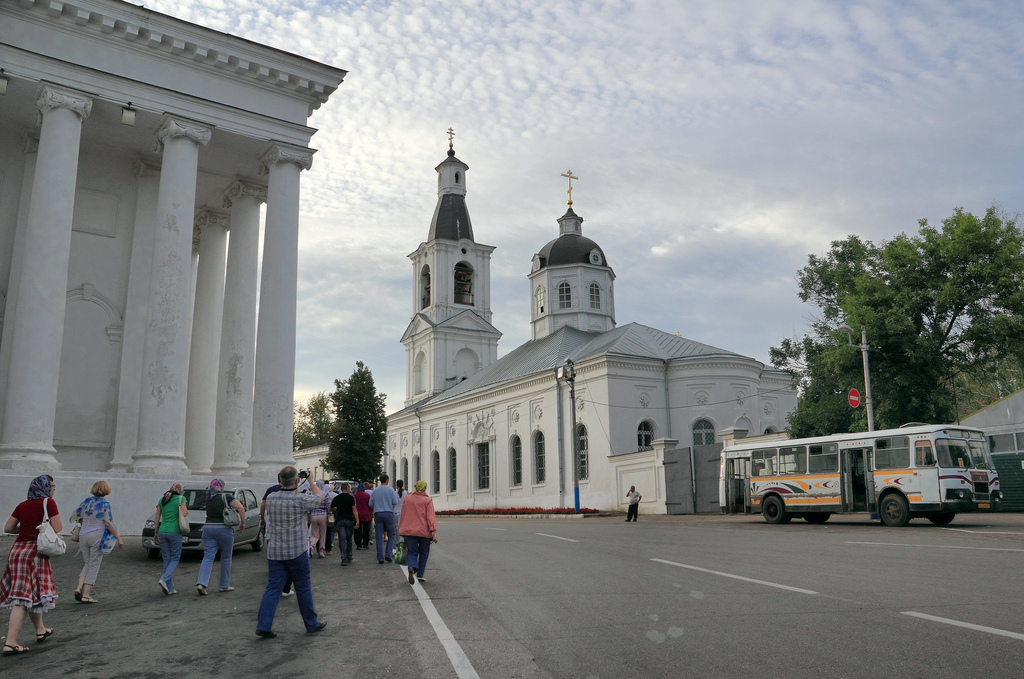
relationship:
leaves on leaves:
[793, 351, 841, 425] [769, 206, 1024, 439]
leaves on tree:
[872, 322, 912, 403] [786, 199, 1013, 433]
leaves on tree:
[816, 240, 883, 325] [786, 199, 1013, 433]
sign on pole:
[842, 381, 868, 407] [849, 329, 882, 436]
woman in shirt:
[149, 474, 189, 600] [149, 493, 189, 530]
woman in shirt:
[67, 474, 126, 600] [79, 497, 105, 534]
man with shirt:
[324, 471, 372, 571] [335, 493, 357, 533]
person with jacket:
[391, 471, 439, 567] [399, 491, 438, 539]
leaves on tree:
[777, 210, 1020, 416] [775, 197, 1015, 450]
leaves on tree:
[769, 206, 1024, 439] [775, 214, 1020, 416]